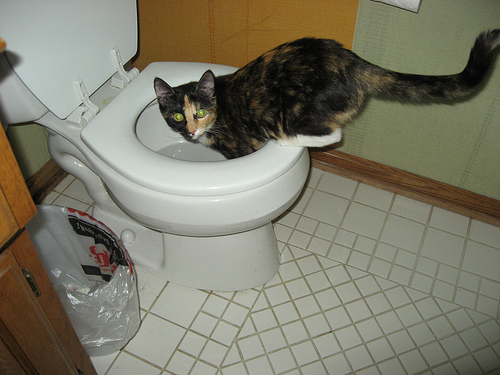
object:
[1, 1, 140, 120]
seat cover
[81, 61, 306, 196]
seat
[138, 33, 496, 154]
cat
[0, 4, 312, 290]
toilet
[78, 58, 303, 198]
seat up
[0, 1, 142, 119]
lid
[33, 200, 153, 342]
can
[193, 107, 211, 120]
green eyes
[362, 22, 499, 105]
tail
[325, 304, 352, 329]
tile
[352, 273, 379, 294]
tile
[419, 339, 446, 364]
tile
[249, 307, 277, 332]
tile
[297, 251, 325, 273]
tile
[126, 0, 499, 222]
wall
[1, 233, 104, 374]
cabinet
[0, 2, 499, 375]
bathroom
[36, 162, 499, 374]
floor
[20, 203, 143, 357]
bag